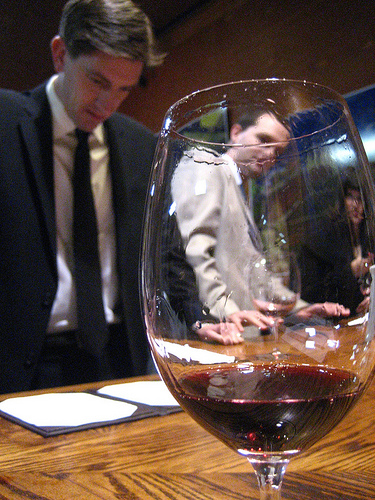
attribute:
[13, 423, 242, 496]
wood — Brown 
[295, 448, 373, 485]
wood — Brown 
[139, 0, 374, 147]
wall — Brown 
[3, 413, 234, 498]
wood finish — Brown 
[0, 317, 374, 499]
wood — Brown , stained, finished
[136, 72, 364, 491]
glass — wine glass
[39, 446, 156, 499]
wood finish — stained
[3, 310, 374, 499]
wood finish — Brown 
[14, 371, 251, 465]
menu — paper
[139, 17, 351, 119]
wall — White 